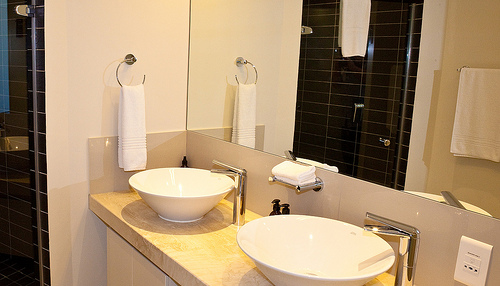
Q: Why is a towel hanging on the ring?
A: To dry hands.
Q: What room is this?
A: Bathroom.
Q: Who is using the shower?
A: No one.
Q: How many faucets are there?
A: 2.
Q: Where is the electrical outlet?
A: Far right bottom foreground.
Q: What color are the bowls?
A: White.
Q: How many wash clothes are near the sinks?
A: 2.